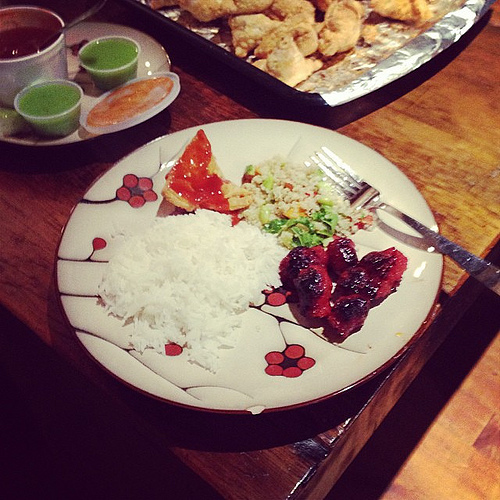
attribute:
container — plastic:
[13, 76, 81, 137]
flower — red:
[260, 340, 314, 380]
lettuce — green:
[273, 212, 348, 244]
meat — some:
[284, 235, 394, 317]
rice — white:
[100, 209, 286, 374]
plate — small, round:
[26, 45, 157, 141]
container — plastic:
[76, 33, 141, 91]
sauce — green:
[16, 81, 80, 138]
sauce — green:
[80, 37, 138, 90]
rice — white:
[116, 214, 264, 334]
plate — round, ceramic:
[31, 105, 451, 424]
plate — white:
[57, 117, 451, 411]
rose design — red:
[103, 163, 152, 220]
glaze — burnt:
[286, 246, 321, 305]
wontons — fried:
[178, 3, 430, 82]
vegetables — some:
[246, 155, 343, 245]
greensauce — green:
[11, 77, 83, 134]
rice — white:
[95, 196, 289, 368]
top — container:
[74, 62, 191, 144]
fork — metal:
[303, 145, 498, 297]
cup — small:
[80, 36, 138, 87]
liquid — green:
[26, 85, 79, 116]